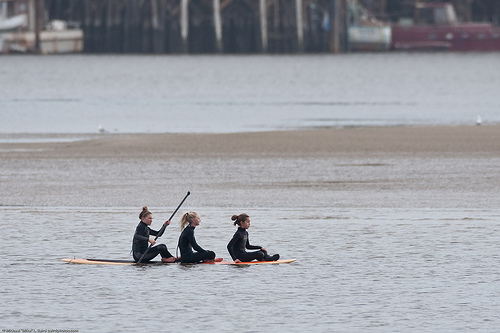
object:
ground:
[321, 226, 338, 242]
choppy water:
[0, 54, 499, 333]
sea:
[4, 52, 499, 332]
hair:
[177, 211, 196, 232]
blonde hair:
[179, 211, 199, 227]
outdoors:
[0, 0, 499, 330]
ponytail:
[179, 212, 189, 228]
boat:
[389, 24, 500, 53]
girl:
[226, 213, 280, 264]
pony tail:
[230, 214, 239, 226]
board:
[57, 255, 300, 266]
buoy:
[474, 111, 483, 127]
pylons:
[24, 0, 355, 55]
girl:
[177, 211, 222, 263]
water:
[0, 50, 499, 331]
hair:
[228, 212, 249, 226]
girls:
[129, 206, 177, 265]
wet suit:
[132, 221, 174, 263]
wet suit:
[179, 225, 216, 264]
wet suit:
[227, 227, 277, 263]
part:
[337, 255, 372, 301]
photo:
[0, 0, 500, 333]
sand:
[0, 119, 499, 184]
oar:
[135, 192, 191, 265]